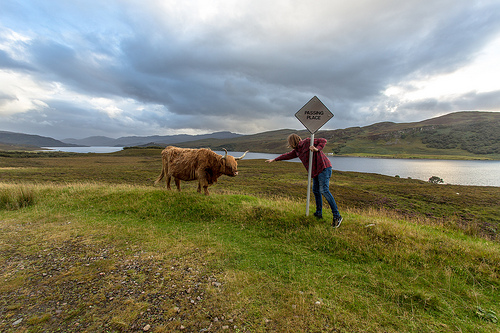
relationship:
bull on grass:
[151, 136, 254, 194] [3, 146, 495, 331]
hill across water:
[63, 125, 245, 144] [35, 138, 128, 155]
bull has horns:
[151, 136, 254, 194] [222, 144, 253, 161]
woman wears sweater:
[269, 126, 351, 230] [278, 138, 338, 176]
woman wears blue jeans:
[269, 126, 351, 230] [306, 167, 342, 221]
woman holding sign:
[269, 126, 351, 230] [294, 91, 334, 229]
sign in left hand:
[294, 91, 334, 229] [304, 142, 320, 155]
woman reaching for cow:
[264, 131, 344, 228] [151, 136, 254, 194]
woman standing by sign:
[264, 131, 344, 228] [294, 91, 334, 229]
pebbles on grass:
[1, 224, 295, 327] [3, 146, 495, 331]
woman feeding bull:
[264, 131, 344, 228] [151, 136, 254, 194]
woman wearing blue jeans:
[264, 131, 344, 228] [306, 167, 342, 221]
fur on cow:
[163, 144, 214, 182] [151, 136, 254, 194]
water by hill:
[35, 138, 128, 155] [63, 125, 245, 144]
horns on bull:
[222, 144, 253, 161] [151, 136, 254, 194]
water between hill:
[35, 138, 128, 155] [63, 125, 245, 144]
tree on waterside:
[427, 174, 448, 187] [250, 153, 497, 195]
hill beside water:
[63, 125, 245, 144] [35, 138, 128, 155]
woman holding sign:
[264, 131, 344, 228] [294, 91, 334, 229]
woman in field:
[264, 131, 344, 228] [3, 146, 495, 331]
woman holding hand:
[269, 126, 351, 230] [259, 158, 277, 166]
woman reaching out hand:
[269, 126, 351, 230] [263, 158, 277, 165]